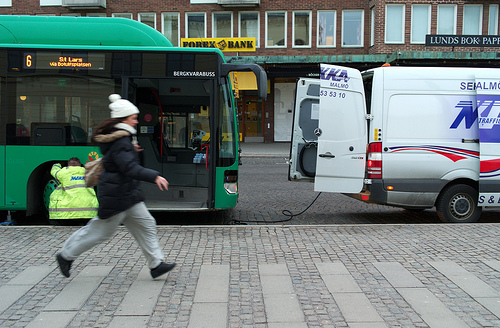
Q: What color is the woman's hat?
A: White.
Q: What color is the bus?
A: Green and black.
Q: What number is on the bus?
A: Six.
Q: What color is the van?
A: White.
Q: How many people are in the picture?
A: Two.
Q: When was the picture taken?
A: Day time.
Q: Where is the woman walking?
A: On a sidewalk.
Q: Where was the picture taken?
A: On the sidewalk.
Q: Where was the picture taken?
A: On a sidewalk.